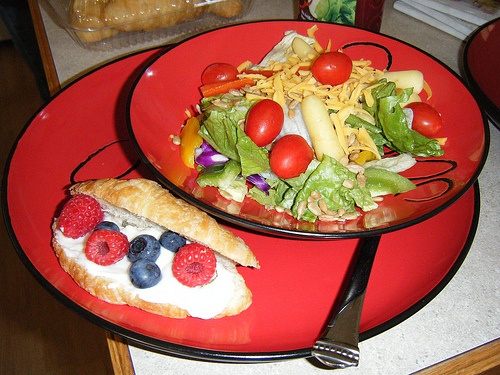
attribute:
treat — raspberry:
[43, 176, 261, 320]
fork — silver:
[313, 241, 381, 374]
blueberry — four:
[125, 229, 182, 293]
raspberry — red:
[57, 194, 223, 299]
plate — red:
[7, 18, 498, 366]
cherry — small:
[49, 192, 215, 298]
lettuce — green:
[187, 73, 453, 211]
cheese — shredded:
[260, 40, 378, 124]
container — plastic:
[34, 3, 271, 37]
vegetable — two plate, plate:
[185, 18, 446, 219]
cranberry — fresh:
[195, 36, 444, 174]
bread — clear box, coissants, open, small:
[52, 171, 266, 322]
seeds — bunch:
[287, 174, 385, 225]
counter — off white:
[54, 34, 498, 375]